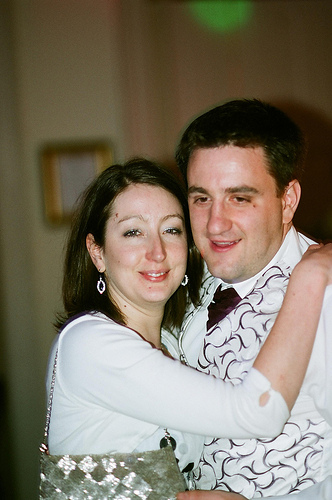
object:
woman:
[43, 156, 332, 500]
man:
[175, 98, 330, 500]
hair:
[174, 98, 305, 200]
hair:
[50, 153, 204, 335]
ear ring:
[96, 274, 106, 294]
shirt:
[44, 311, 290, 477]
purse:
[37, 314, 193, 499]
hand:
[289, 238, 331, 286]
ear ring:
[179, 274, 189, 287]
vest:
[175, 225, 331, 499]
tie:
[206, 280, 242, 332]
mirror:
[37, 135, 118, 228]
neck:
[103, 285, 165, 339]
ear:
[85, 232, 107, 274]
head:
[85, 159, 189, 308]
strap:
[39, 312, 109, 454]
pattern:
[207, 443, 317, 483]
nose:
[206, 198, 233, 235]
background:
[0, 2, 331, 94]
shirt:
[177, 222, 331, 498]